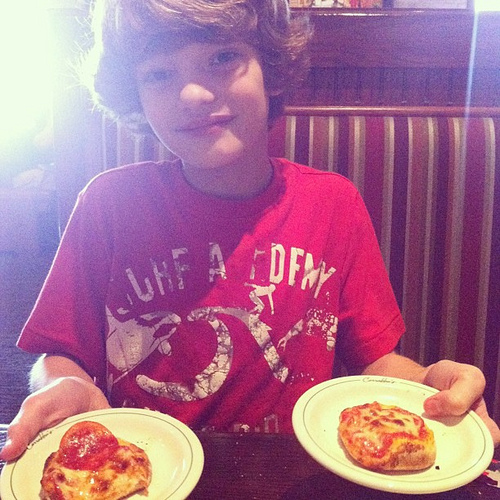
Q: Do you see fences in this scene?
A: No, there are no fences.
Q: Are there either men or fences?
A: No, there are no fences or men.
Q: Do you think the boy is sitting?
A: Yes, the boy is sitting.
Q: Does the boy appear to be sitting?
A: Yes, the boy is sitting.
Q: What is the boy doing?
A: The boy is sitting.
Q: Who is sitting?
A: The boy is sitting.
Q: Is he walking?
A: No, the boy is sitting.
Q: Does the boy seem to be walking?
A: No, the boy is sitting.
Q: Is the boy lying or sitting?
A: The boy is sitting.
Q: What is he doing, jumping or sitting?
A: The boy is sitting.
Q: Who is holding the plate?
A: The boy is holding the plate.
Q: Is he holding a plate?
A: Yes, the boy is holding a plate.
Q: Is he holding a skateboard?
A: No, the boy is holding a plate.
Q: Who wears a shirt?
A: The boy wears a shirt.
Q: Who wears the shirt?
A: The boy wears a shirt.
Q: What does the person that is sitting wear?
A: The boy wears a shirt.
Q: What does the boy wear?
A: The boy wears a shirt.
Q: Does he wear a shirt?
A: Yes, the boy wears a shirt.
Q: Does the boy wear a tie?
A: No, the boy wears a shirt.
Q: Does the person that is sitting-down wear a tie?
A: No, the boy wears a shirt.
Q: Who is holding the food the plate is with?
A: The boy is holding the pizza.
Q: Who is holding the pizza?
A: The boy is holding the pizza.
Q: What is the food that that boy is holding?
A: The food is a pizza.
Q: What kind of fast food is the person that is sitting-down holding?
A: The boy is holding the pizza.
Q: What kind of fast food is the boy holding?
A: The boy is holding the pizza.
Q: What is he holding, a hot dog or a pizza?
A: The boy is holding a pizza.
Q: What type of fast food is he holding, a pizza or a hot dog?
A: The boy is holding a pizza.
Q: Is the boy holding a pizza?
A: Yes, the boy is holding a pizza.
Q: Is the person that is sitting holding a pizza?
A: Yes, the boy is holding a pizza.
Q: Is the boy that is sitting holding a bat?
A: No, the boy is holding a pizza.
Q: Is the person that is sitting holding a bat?
A: No, the boy is holding a pizza.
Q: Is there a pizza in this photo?
A: Yes, there is a pizza.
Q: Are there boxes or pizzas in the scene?
A: Yes, there is a pizza.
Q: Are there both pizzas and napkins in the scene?
A: No, there is a pizza but no napkins.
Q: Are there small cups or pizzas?
A: Yes, there is a small pizza.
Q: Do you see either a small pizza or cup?
A: Yes, there is a small pizza.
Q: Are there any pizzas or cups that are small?
A: Yes, the pizza is small.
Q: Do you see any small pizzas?
A: Yes, there is a small pizza.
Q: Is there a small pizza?
A: Yes, there is a small pizza.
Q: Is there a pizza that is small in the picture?
A: Yes, there is a small pizza.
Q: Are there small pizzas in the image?
A: Yes, there is a small pizza.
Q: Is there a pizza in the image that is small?
A: Yes, there is a pizza that is small.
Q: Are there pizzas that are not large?
A: Yes, there is a small pizza.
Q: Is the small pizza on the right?
A: Yes, the pizza is on the right of the image.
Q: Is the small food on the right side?
A: Yes, the pizza is on the right of the image.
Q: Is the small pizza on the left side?
A: No, the pizza is on the right of the image.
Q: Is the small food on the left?
A: No, the pizza is on the right of the image.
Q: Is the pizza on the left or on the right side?
A: The pizza is on the right of the image.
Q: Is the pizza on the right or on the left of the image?
A: The pizza is on the right of the image.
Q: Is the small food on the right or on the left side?
A: The pizza is on the right of the image.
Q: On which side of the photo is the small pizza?
A: The pizza is on the right of the image.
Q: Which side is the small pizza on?
A: The pizza is on the right of the image.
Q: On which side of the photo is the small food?
A: The pizza is on the right of the image.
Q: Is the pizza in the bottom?
A: Yes, the pizza is in the bottom of the image.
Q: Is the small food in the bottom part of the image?
A: Yes, the pizza is in the bottom of the image.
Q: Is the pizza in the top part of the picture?
A: No, the pizza is in the bottom of the image.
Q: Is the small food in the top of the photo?
A: No, the pizza is in the bottom of the image.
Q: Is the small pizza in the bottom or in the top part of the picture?
A: The pizza is in the bottom of the image.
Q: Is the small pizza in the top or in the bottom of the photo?
A: The pizza is in the bottom of the image.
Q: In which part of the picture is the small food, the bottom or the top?
A: The pizza is in the bottom of the image.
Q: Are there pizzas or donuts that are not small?
A: No, there is a pizza but it is small.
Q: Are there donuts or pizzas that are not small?
A: No, there is a pizza but it is small.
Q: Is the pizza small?
A: Yes, the pizza is small.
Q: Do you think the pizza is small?
A: Yes, the pizza is small.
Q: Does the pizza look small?
A: Yes, the pizza is small.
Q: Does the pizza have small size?
A: Yes, the pizza is small.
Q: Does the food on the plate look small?
A: Yes, the pizza is small.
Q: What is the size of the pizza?
A: The pizza is small.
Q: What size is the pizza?
A: The pizza is small.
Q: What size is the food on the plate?
A: The pizza is small.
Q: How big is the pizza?
A: The pizza is small.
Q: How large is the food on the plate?
A: The pizza is small.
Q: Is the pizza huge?
A: No, the pizza is small.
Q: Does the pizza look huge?
A: No, the pizza is small.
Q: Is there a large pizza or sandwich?
A: No, there is a pizza but it is small.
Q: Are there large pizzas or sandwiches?
A: No, there is a pizza but it is small.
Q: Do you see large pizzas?
A: No, there is a pizza but it is small.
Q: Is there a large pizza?
A: No, there is a pizza but it is small.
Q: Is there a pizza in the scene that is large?
A: No, there is a pizza but it is small.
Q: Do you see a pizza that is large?
A: No, there is a pizza but it is small.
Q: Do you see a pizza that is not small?
A: No, there is a pizza but it is small.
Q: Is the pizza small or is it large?
A: The pizza is small.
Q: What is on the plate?
A: The pizza is on the plate.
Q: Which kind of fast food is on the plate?
A: The food is a pizza.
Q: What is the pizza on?
A: The pizza is on the plate.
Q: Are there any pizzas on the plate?
A: Yes, there is a pizza on the plate.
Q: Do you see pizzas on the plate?
A: Yes, there is a pizza on the plate.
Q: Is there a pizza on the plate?
A: Yes, there is a pizza on the plate.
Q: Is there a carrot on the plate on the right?
A: No, there is a pizza on the plate.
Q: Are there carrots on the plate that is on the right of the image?
A: No, there is a pizza on the plate.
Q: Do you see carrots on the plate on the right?
A: No, there is a pizza on the plate.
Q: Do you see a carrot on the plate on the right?
A: No, there is a pizza on the plate.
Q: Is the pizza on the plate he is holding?
A: Yes, the pizza is on the plate.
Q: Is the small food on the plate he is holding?
A: Yes, the pizza is on the plate.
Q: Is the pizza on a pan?
A: No, the pizza is on the plate.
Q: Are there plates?
A: Yes, there is a plate.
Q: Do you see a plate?
A: Yes, there is a plate.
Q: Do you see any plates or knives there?
A: Yes, there is a plate.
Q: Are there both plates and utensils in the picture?
A: No, there is a plate but no utensils.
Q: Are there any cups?
A: No, there are no cups.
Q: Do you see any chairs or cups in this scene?
A: No, there are no cups or chairs.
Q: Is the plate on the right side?
A: Yes, the plate is on the right of the image.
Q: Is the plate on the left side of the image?
A: No, the plate is on the right of the image.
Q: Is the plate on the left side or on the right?
A: The plate is on the right of the image.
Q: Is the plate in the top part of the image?
A: No, the plate is in the bottom of the image.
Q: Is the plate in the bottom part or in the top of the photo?
A: The plate is in the bottom of the image.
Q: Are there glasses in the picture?
A: No, there are no glasses.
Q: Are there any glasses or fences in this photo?
A: No, there are no glasses or fences.